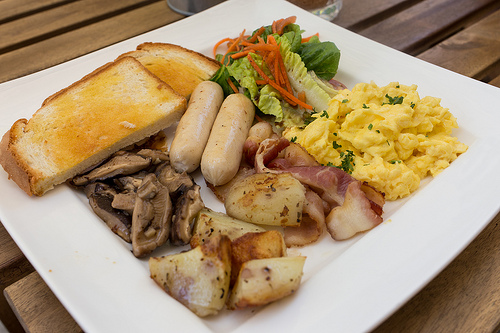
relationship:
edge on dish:
[60, 254, 171, 333] [0, 0, 498, 330]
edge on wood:
[8, 299, 35, 333] [366, 17, 494, 97]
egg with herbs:
[309, 82, 436, 195] [381, 87, 411, 118]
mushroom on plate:
[111, 172, 171, 257] [0, 1, 484, 331]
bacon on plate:
[246, 128, 386, 231] [0, 1, 484, 331]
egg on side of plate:
[282, 80, 469, 201] [0, 1, 484, 331]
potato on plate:
[223, 169, 310, 224] [0, 1, 484, 331]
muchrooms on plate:
[71, 153, 151, 185] [0, 1, 484, 331]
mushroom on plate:
[129, 170, 171, 257] [0, 1, 484, 331]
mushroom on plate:
[85, 178, 137, 245] [0, 1, 484, 331]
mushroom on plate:
[155, 163, 195, 193] [0, 1, 484, 331]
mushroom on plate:
[132, 134, 171, 163] [0, 1, 484, 331]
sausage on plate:
[175, 67, 282, 189] [0, 1, 484, 331]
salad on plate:
[206, 10, 343, 130] [0, 1, 484, 331]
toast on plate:
[0, 41, 222, 199] [0, 1, 484, 331]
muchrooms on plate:
[74, 140, 207, 257] [0, 1, 484, 331]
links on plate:
[168, 85, 235, 185] [0, 1, 484, 331]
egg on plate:
[282, 80, 469, 201] [0, 1, 484, 331]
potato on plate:
[158, 164, 311, 306] [425, 49, 485, 211]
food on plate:
[133, 32, 401, 263] [406, 185, 478, 257]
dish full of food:
[0, 0, 499, 332] [95, 43, 404, 279]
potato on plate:
[174, 175, 305, 308] [0, 1, 484, 331]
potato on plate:
[150, 245, 232, 318] [0, 1, 484, 331]